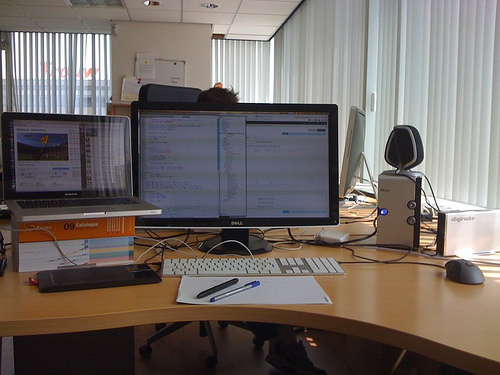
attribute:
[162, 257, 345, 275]
keyboard — white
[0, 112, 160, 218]
computer — laptop, grey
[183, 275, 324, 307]
paper — white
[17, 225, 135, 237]
book — orange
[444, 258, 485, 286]
mouse — grey, black, silver